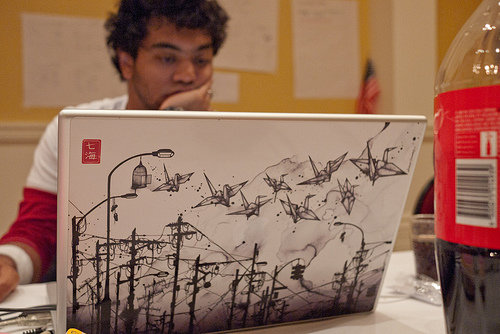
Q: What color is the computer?
A: Silver.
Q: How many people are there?
A: One.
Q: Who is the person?
A: A man.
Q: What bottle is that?
A: Coke.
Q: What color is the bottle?
A: Red.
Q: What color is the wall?
A: Cream.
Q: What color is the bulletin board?
A: Yellow.